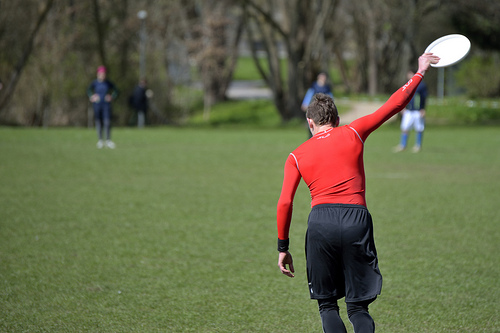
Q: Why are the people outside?
A: They are playing a game.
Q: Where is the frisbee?
A: In the man's hand.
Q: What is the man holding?
A: A frisbee.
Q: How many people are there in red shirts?
A: One.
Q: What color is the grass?
A: Green.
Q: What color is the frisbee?
A: White.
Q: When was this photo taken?
A: During the daytime.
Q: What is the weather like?
A: Sunny.